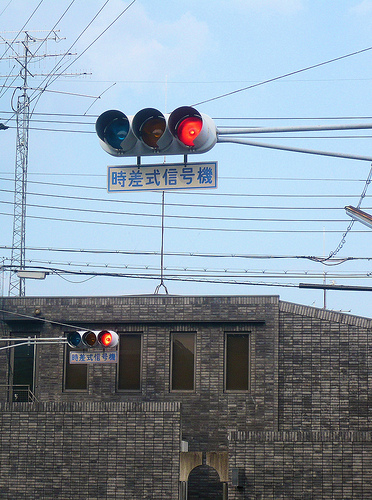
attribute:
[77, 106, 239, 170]
traffic light — red, gray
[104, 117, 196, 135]
colors — 3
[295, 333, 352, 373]
building — stone, gray brick, gray, brown, brick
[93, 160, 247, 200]
sign — blue, white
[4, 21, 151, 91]
wires — electricity, gray, telephone, electrical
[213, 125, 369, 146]
pole — metal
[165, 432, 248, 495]
archway — entrance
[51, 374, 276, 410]
windows — rectangular, tinted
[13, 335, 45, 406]
door — rectangular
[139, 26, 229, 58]
clouds — white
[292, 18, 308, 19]
sky — blue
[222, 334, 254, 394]
window — glass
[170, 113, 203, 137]
light — red